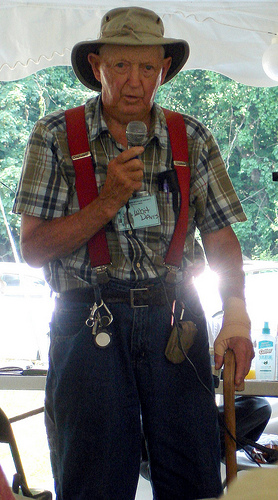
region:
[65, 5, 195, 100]
green hat on old man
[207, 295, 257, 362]
bandage on man's hand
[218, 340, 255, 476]
wooden cane in man's hand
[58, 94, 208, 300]
red suspenders on man's pants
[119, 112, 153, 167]
microphone in man's hand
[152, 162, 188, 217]
glasses case in pocket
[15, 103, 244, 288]
plaid short sleeved shirt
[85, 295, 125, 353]
key ring on belt loop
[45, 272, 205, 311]
black belt on blue jeans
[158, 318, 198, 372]
case handing from pants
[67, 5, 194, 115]
man in a frumpy hat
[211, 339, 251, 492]
hand holding a wooden cane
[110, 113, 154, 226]
a microphone in a man's hand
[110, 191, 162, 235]
name tag on a shirt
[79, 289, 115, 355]
clips on a belt loop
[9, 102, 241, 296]
green white and black plaid shirt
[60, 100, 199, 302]
man with red suspenders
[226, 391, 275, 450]
the knee of a seated man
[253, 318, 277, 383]
blue, red and white squeeze bottle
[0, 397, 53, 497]
chair sitting against the table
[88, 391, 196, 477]
the man has a blue jeans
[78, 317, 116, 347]
the man has keys hanging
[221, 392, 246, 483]
the walking stick is wooden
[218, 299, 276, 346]
the man has a brown bandage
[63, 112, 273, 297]
the man is holding a microphone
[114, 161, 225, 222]
he has a badge around his neck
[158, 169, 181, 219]
the is a pen in his shirtpocket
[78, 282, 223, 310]
his belt is black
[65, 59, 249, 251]
the man is old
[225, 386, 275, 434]
a person is sited down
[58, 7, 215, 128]
old man in green hat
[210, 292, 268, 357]
bandage on man's wrist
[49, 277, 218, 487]
blue jeans on man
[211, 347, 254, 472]
wood cane in man's hand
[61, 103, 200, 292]
red suspenders attached to pants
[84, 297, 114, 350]
key chain on belt loop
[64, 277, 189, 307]
black belt on pants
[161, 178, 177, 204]
pen in shirt pocket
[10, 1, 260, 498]
old man holding brown wooden cane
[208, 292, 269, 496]
brown wooden cane in bandaged hand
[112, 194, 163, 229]
plastic covered name tag with black writing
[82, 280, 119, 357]
silver keys hanging from pant loop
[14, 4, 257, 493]
old man wearing brown plaid shirt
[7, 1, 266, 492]
old man holding microphone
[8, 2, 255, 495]
old man wearing red suspenders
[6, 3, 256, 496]
old man wearing tan hat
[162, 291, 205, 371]
brown cell phone case hanging from silver hook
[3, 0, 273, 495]
old man under white tent